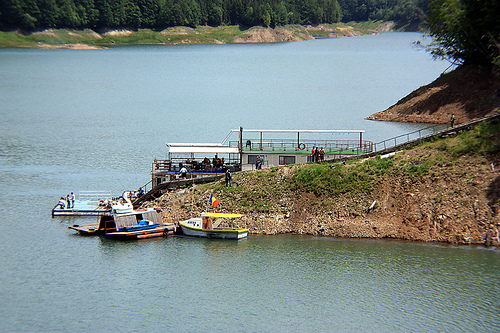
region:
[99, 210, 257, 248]
boats in the water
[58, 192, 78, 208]
people standing on the dock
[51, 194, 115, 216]
a boat dock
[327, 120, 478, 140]
a fence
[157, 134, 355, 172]
a large boat in the water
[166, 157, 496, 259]
a hill of dirt and grass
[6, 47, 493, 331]
a body of water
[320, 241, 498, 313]
small waves in the water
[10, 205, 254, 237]
the boats are docked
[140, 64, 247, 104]
large body of water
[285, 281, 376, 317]
the water is calm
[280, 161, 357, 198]
grass on the shore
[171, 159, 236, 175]
people in the shade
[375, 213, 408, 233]
dirt on the shore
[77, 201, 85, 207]
the dock is blue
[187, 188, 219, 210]
flag on the boat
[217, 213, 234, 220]
the roof is yellow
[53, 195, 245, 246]
the boats are docked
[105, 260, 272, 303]
large body of water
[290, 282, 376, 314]
the water is calm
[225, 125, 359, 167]
building on the land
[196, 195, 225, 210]
flag on the boat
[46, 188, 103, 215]
people on the dock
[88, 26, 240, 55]
grass on the shore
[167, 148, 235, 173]
people under the roof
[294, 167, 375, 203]
moss on the shore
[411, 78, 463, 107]
shadows of the trees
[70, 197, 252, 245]
Boats in the water by the shore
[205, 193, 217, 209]
A colorful flag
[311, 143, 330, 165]
People standing by the shore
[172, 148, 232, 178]
People standing on the pier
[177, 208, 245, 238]
A white and yellow boat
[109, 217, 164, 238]
A blue and white boat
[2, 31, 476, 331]
A large body of water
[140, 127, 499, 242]
A piece of land stretching out into the water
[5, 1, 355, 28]
A line of trees across the water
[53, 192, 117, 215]
A platform on the water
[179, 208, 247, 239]
yellow and white boat with yellow canopy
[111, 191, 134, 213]
small white swan boat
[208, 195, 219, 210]
red, yellow, and blue flag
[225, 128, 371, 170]
green roofed building with metal guard rail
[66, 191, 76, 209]
two people on a floating dock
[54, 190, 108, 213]
light blue floating dock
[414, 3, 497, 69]
green foliage from a large tree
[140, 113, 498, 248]
grassy and rocky shoreline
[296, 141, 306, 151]
small round life preserver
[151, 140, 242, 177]
white roofed structure full of people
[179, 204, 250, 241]
a boat on the water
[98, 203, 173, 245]
a boat on the water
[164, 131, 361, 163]
a boat on the water